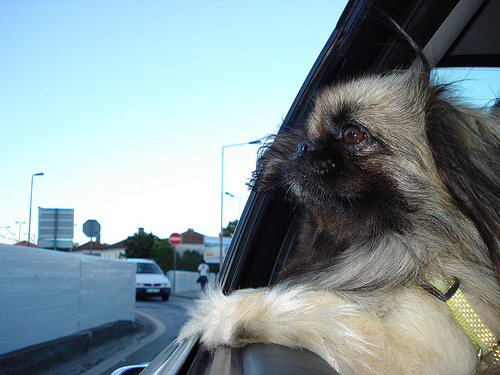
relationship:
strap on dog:
[412, 266, 499, 366] [204, 67, 498, 373]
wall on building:
[0, 243, 138, 356] [5, 238, 143, 358]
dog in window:
[169, 51, 499, 373] [246, 41, 497, 364]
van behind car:
[118, 252, 172, 305] [152, 0, 495, 371]